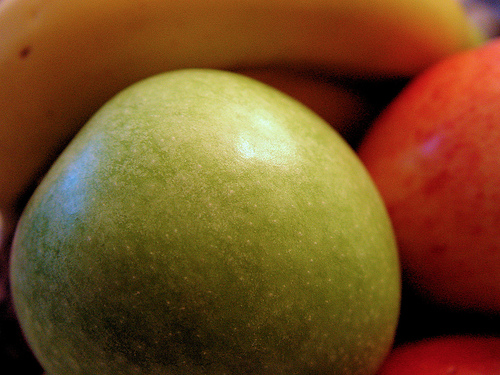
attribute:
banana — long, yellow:
[0, 1, 490, 134]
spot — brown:
[9, 28, 43, 73]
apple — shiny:
[2, 82, 407, 374]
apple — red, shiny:
[359, 36, 499, 310]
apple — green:
[12, 98, 421, 374]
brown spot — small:
[16, 41, 36, 61]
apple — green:
[0, 52, 417, 374]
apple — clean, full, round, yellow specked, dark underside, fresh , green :
[23, 61, 397, 373]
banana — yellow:
[3, 3, 483, 74]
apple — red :
[358, 35, 495, 215]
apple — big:
[19, 33, 433, 373]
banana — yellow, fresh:
[248, 10, 333, 76]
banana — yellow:
[3, 1, 478, 211]